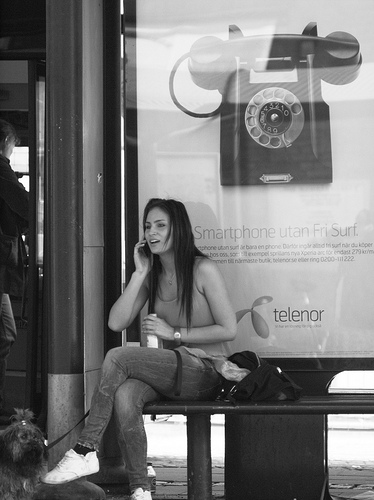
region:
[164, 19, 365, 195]
a printed image of a telephone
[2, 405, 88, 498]
a small dog on a leash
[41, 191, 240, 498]
a woman sitting on a bench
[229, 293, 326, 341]
a corporate logo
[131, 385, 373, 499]
a black metal bench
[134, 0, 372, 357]
an outdoor advertisement billboard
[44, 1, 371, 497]
a bus stop shelter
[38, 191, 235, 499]
a woman talking on a cell phone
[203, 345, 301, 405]
a black purse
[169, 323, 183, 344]
a wrist watch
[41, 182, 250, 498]
woman sitting on bench with phone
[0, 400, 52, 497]
little dog sitting on the ground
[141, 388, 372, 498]
bench woman is sitting on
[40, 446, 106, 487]
white sneaker of a woman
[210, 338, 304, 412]
opened purse of a woman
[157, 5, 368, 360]
advertisement by a bus stop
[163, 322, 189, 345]
wrist watch on left arm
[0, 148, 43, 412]
passenger boarding a bus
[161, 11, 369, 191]
image of a vintage telephone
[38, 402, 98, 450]
leash of a dog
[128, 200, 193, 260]
The woman is holding a phone to her ear.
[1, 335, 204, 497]
The dog is on a lease.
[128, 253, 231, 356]
The woman is wearing a tank top.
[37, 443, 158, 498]
The woman has shoes on her feet.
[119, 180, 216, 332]
The woman is wearing her hair down.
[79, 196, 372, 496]
The woman is sitting on a bench.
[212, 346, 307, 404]
An open bag is on the bench next to the woman.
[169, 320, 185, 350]
A watch is on the woman's wrist.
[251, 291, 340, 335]
The text on the sign says telenor.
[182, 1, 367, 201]
A picture of a telephone is on the sign.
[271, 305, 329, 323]
billboard text reading telenor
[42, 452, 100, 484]
white sneakers with white laces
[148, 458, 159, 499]
bottle on the ground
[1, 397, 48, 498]
small dog with a ponytail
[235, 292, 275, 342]
logo graphic on billboard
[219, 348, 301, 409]
black bag resting on bench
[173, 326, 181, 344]
watch with a white face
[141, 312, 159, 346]
white object in woman's hand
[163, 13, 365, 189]
large black telephone graphic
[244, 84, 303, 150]
telephone dial graphic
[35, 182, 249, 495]
a young girl talking on the phone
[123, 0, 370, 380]
advertiseing sign with a black house phone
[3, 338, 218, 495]
a dog on a leash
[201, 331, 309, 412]
an open purse on the bench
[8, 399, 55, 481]
a dog with a ponytail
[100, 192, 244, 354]
a woman in a tank top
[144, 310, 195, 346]
a watch on a womans left wrist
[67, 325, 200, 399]
leash laying on girls leg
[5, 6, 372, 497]
a black and white picture